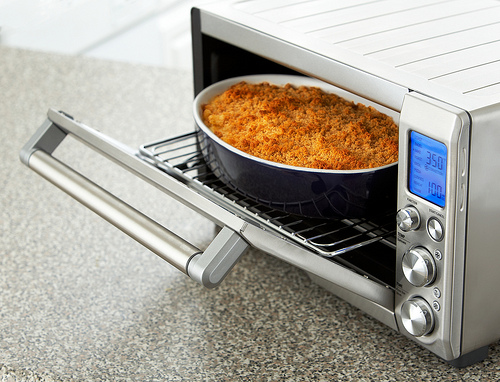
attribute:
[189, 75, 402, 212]
dish — black, white, ceramic, blue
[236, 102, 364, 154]
food — fried, delicious, brow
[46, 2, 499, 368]
oven — silver, grooved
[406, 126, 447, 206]
readings — digital, blue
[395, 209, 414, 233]
knob — siver, silver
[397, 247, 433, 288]
knob — siver, silver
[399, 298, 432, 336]
knob — siver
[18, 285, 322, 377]
granite — multicolored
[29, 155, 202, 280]
handle — siver, silver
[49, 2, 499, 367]
microwave — open, metallic, silver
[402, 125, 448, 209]
light — on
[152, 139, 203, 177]
grill — metallic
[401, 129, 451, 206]
gauge — blue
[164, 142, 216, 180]
rack — metal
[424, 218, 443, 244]
button — silver, circular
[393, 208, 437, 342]
dials — silver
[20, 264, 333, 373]
countertop — gray, gra